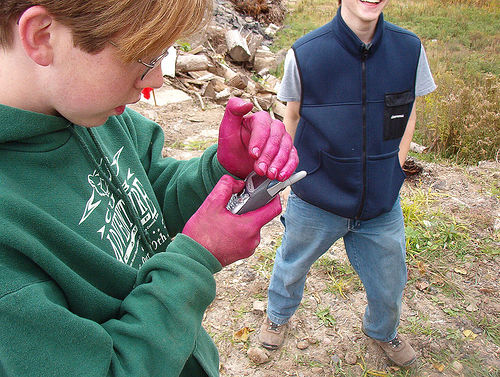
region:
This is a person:
[274, 3, 435, 370]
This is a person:
[277, 4, 430, 374]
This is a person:
[8, 5, 324, 373]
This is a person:
[275, 5, 453, 373]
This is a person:
[3, 4, 295, 371]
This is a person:
[273, 1, 441, 374]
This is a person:
[2, 2, 307, 374]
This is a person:
[275, 4, 448, 374]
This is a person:
[1, 5, 303, 375]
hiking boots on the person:
[371, 324, 418, 374]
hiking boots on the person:
[243, 317, 310, 362]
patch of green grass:
[427, 231, 442, 251]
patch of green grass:
[421, 224, 438, 240]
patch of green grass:
[454, 151, 471, 178]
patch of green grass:
[443, 137, 473, 165]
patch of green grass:
[460, 36, 480, 56]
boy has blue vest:
[290, 25, 390, 215]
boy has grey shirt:
[277, 46, 305, 103]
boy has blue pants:
[268, 177, 405, 337]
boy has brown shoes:
[382, 325, 420, 372]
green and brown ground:
[425, 209, 484, 353]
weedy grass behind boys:
[426, 0, 485, 155]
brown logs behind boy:
[182, 24, 280, 131]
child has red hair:
[5, 3, 195, 40]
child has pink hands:
[148, 86, 296, 280]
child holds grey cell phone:
[222, 152, 320, 244]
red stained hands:
[167, 88, 316, 292]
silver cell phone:
[198, 148, 315, 215]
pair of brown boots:
[232, 296, 433, 376]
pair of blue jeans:
[248, 183, 416, 343]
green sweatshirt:
[0, 92, 252, 367]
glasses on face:
[88, 26, 175, 90]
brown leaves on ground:
[425, 285, 485, 343]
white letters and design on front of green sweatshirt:
[57, 142, 179, 294]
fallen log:
[208, 21, 262, 68]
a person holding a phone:
[224, 136, 304, 230]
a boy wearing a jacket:
[276, 11, 426, 303]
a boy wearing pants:
[282, 57, 419, 308]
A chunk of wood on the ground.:
[214, 87, 236, 101]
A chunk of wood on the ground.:
[228, 75, 247, 85]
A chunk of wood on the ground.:
[203, 81, 219, 98]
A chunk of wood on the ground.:
[248, 94, 268, 109]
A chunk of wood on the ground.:
[245, 34, 268, 53]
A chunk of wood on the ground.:
[228, 27, 253, 57]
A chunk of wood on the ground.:
[176, 53, 223, 74]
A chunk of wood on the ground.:
[190, 75, 214, 94]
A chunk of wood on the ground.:
[253, 92, 278, 105]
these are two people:
[34, 0, 419, 370]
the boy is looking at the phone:
[64, 22, 302, 312]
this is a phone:
[206, 189, 316, 249]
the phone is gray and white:
[227, 144, 307, 209]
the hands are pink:
[119, 34, 322, 203]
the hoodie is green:
[32, 142, 170, 321]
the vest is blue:
[286, 22, 416, 261]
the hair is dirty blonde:
[73, 0, 200, 62]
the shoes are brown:
[223, 273, 427, 371]